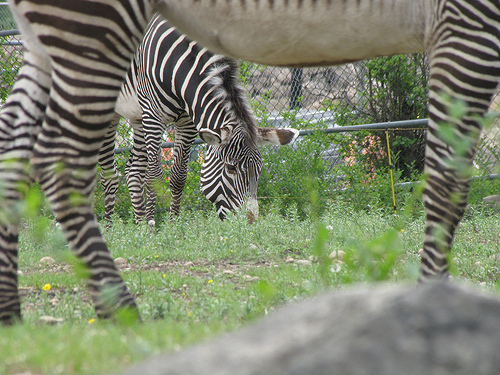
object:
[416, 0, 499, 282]
leg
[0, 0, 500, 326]
zebra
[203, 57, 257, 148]
zebra mane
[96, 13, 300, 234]
zebra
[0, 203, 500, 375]
grass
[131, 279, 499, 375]
boulder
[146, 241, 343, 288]
patch